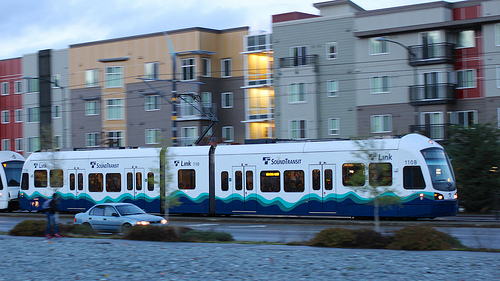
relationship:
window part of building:
[286, 81, 307, 105] [269, 0, 484, 144]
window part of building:
[286, 81, 304, 102] [22, 25, 466, 160]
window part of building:
[325, 42, 339, 61] [22, 25, 466, 160]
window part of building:
[327, 118, 340, 135] [22, 25, 466, 160]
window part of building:
[220, 92, 233, 108] [22, 25, 466, 160]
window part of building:
[460, 30, 475, 50] [22, 25, 466, 160]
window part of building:
[368, 35, 391, 56] [1, 7, 498, 138]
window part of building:
[325, 40, 339, 63] [269, 1, 496, 133]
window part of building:
[326, 81, 339, 98] [269, 1, 496, 133]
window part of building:
[326, 117, 344, 136] [269, 1, 496, 133]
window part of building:
[368, 35, 388, 55] [269, 1, 496, 133]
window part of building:
[367, 76, 390, 96] [269, 1, 496, 133]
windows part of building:
[47, 14, 207, 206] [18, 28, 496, 180]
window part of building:
[368, 35, 391, 56] [269, 0, 484, 144]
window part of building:
[369, 75, 392, 94] [269, 0, 484, 144]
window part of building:
[368, 110, 396, 135] [269, 0, 484, 144]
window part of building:
[286, 117, 311, 140] [269, 0, 484, 144]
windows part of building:
[0, 104, 42, 128] [1, 2, 496, 176]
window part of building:
[218, 89, 233, 108] [1, 7, 498, 138]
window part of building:
[222, 57, 231, 79] [1, 7, 498, 138]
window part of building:
[221, 125, 235, 142] [1, 7, 498, 138]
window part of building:
[325, 42, 339, 61] [1, 7, 498, 138]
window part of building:
[325, 78, 338, 97] [1, 7, 498, 138]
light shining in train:
[264, 170, 278, 177] [1, 130, 463, 216]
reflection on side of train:
[28, 198, 38, 207] [46, 145, 464, 222]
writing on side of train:
[260, 157, 302, 166] [15, 96, 479, 274]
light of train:
[433, 192, 444, 201] [1, 130, 463, 216]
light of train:
[454, 192, 461, 200] [1, 130, 463, 216]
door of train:
[310, 164, 320, 209] [1, 130, 463, 216]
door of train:
[322, 164, 336, 211] [1, 130, 463, 216]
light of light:
[489, 167, 499, 173] [483, 163, 498, 178]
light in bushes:
[483, 163, 498, 178] [450, 128, 497, 213]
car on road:
[71, 200, 168, 230] [2, 208, 499, 245]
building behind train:
[0, 0, 499, 160] [1, 130, 463, 216]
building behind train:
[0, 32, 70, 146] [1, 130, 463, 216]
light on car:
[134, 220, 141, 224] [70, 192, 194, 234]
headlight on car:
[141, 220, 150, 225] [70, 192, 194, 234]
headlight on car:
[161, 219, 168, 224] [70, 192, 194, 234]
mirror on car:
[110, 211, 119, 217] [72, 202, 167, 232]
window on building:
[369, 75, 392, 94] [269, 0, 484, 144]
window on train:
[85, 172, 105, 191] [1, 130, 463, 216]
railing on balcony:
[405, 81, 452, 95] [399, 81, 461, 111]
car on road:
[73, 203, 169, 236] [1, 212, 498, 249]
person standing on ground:
[43, 190, 65, 237] [2, 230, 495, 277]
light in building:
[250, 55, 268, 60] [26, 35, 248, 192]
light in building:
[256, 57, 272, 79] [26, 35, 248, 192]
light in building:
[250, 88, 260, 108] [26, 35, 248, 192]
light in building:
[251, 88, 272, 95] [26, 35, 248, 192]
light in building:
[259, 122, 274, 138] [26, 35, 248, 192]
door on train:
[232, 162, 257, 215] [18, 131, 460, 221]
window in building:
[141, 93, 161, 113] [68, 25, 249, 149]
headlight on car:
[135, 218, 150, 226] [73, 203, 169, 236]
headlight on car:
[158, 217, 168, 224] [73, 203, 169, 236]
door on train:
[318, 165, 339, 215] [18, 131, 460, 221]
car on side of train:
[73, 203, 169, 236] [1, 130, 463, 216]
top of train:
[32, 132, 437, 160] [1, 130, 463, 216]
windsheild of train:
[422, 154, 455, 189] [18, 131, 460, 221]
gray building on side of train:
[272, 0, 487, 140] [1, 130, 463, 216]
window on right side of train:
[267, 163, 308, 203] [18, 131, 460, 221]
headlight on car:
[141, 220, 150, 225] [72, 187, 151, 257]